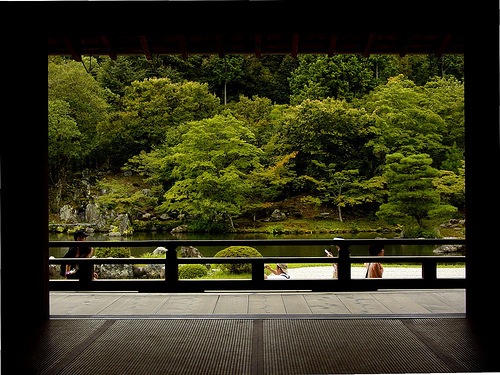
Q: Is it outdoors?
A: Yes, it is outdoors.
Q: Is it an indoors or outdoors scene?
A: It is outdoors.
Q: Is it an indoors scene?
A: No, it is outdoors.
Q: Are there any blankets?
A: No, there are no blankets.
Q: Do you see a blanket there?
A: No, there are no blankets.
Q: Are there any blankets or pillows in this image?
A: No, there are no blankets or pillows.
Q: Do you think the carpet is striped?
A: Yes, the carpet is striped.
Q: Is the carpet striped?
A: Yes, the carpet is striped.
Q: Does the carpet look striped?
A: Yes, the carpet is striped.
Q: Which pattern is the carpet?
A: The carpet is striped.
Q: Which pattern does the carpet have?
A: The carpet has striped pattern.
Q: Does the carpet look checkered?
A: No, the carpet is striped.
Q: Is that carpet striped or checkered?
A: The carpet is striped.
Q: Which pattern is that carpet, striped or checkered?
A: The carpet is striped.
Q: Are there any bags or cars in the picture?
A: No, there are no cars or bags.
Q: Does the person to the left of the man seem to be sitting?
A: Yes, the person is sitting.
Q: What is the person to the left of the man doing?
A: The person is sitting.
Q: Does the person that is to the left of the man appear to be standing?
A: No, the person is sitting.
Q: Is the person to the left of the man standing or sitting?
A: The person is sitting.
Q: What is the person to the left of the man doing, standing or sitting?
A: The person is sitting.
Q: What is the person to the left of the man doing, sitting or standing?
A: The person is sitting.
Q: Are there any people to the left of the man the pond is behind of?
A: Yes, there is a person to the left of the man.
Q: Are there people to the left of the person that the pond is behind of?
A: Yes, there is a person to the left of the man.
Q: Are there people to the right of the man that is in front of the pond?
A: No, the person is to the left of the man.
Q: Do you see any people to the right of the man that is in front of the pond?
A: No, the person is to the left of the man.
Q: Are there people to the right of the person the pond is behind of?
A: No, the person is to the left of the man.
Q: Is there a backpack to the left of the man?
A: No, there is a person to the left of the man.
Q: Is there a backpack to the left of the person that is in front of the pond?
A: No, there is a person to the left of the man.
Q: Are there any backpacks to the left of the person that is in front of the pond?
A: No, there is a person to the left of the man.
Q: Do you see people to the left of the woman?
A: Yes, there is a person to the left of the woman.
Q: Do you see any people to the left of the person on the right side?
A: Yes, there is a person to the left of the woman.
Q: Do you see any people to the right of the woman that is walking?
A: No, the person is to the left of the woman.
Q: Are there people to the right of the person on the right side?
A: No, the person is to the left of the woman.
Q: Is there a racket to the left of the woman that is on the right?
A: No, there is a person to the left of the woman.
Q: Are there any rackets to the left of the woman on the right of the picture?
A: No, there is a person to the left of the woman.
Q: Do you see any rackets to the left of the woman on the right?
A: No, there is a person to the left of the woman.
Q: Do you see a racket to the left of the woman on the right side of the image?
A: No, there is a person to the left of the woman.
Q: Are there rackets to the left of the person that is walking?
A: No, there is a person to the left of the woman.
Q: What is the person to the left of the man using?
A: The person is using a camera.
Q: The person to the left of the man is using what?
A: The person is using a camera.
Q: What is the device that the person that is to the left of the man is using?
A: The device is a camera.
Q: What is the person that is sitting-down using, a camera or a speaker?
A: The person is using a camera.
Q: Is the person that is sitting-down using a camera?
A: Yes, the person is using a camera.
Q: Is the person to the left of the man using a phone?
A: No, the person is using a camera.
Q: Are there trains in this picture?
A: No, there are no trains.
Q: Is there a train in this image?
A: No, there are no trains.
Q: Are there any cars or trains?
A: No, there are no trains or cars.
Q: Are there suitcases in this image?
A: No, there are no suitcases.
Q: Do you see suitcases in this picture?
A: No, there are no suitcases.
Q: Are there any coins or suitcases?
A: No, there are no suitcases or coins.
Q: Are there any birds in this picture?
A: No, there are no birds.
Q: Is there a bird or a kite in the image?
A: No, there are no birds or kites.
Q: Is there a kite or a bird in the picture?
A: No, there are no birds or kites.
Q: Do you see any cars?
A: No, there are no cars.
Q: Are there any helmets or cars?
A: No, there are no cars or helmets.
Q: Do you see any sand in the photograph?
A: Yes, there is sand.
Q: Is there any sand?
A: Yes, there is sand.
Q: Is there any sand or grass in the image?
A: Yes, there is sand.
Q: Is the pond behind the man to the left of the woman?
A: Yes, the pond is behind the man.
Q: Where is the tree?
A: The tree is on the shore.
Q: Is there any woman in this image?
A: Yes, there is a woman.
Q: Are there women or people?
A: Yes, there is a woman.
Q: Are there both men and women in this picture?
A: Yes, there are both a woman and a man.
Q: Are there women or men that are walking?
A: Yes, the woman is walking.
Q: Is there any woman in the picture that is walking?
A: Yes, there is a woman that is walking.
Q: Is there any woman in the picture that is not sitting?
A: Yes, there is a woman that is walking.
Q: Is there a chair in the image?
A: No, there are no chairs.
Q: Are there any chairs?
A: No, there are no chairs.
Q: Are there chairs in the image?
A: No, there are no chairs.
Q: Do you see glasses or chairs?
A: No, there are no chairs or glasses.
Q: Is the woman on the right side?
A: Yes, the woman is on the right of the image.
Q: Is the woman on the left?
A: No, the woman is on the right of the image.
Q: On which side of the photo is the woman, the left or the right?
A: The woman is on the right of the image.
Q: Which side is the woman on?
A: The woman is on the right of the image.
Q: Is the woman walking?
A: Yes, the woman is walking.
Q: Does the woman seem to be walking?
A: Yes, the woman is walking.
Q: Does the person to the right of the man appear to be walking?
A: Yes, the woman is walking.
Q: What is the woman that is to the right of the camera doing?
A: The woman is walking.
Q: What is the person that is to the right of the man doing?
A: The woman is walking.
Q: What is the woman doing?
A: The woman is walking.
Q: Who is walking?
A: The woman is walking.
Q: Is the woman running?
A: No, the woman is walking.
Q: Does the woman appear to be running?
A: No, the woman is walking.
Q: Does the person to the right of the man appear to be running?
A: No, the woman is walking.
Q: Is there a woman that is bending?
A: No, there is a woman but she is walking.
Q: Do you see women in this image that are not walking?
A: No, there is a woman but she is walking.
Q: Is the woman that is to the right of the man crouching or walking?
A: The woman is walking.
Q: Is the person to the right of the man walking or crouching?
A: The woman is walking.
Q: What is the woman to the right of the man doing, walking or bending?
A: The woman is walking.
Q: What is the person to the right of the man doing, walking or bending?
A: The woman is walking.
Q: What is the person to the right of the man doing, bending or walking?
A: The woman is walking.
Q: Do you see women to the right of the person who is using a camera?
A: Yes, there is a woman to the right of the person.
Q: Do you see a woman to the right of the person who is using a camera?
A: Yes, there is a woman to the right of the person.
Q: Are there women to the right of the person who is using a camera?
A: Yes, there is a woman to the right of the person.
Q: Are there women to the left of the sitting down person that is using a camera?
A: No, the woman is to the right of the person.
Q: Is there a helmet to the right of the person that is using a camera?
A: No, there is a woman to the right of the person.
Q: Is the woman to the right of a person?
A: Yes, the woman is to the right of a person.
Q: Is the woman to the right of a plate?
A: No, the woman is to the right of a person.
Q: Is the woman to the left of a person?
A: No, the woman is to the right of a person.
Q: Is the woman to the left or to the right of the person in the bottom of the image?
A: The woman is to the right of the person.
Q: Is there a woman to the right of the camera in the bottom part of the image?
A: Yes, there is a woman to the right of the camera.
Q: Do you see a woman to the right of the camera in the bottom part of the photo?
A: Yes, there is a woman to the right of the camera.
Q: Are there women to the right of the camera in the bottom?
A: Yes, there is a woman to the right of the camera.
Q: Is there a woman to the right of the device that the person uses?
A: Yes, there is a woman to the right of the camera.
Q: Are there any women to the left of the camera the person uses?
A: No, the woman is to the right of the camera.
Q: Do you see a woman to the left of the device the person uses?
A: No, the woman is to the right of the camera.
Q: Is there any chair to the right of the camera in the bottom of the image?
A: No, there is a woman to the right of the camera.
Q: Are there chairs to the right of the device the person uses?
A: No, there is a woman to the right of the camera.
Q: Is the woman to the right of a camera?
A: Yes, the woman is to the right of a camera.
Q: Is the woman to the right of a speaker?
A: No, the woman is to the right of a camera.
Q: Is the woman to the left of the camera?
A: No, the woman is to the right of the camera.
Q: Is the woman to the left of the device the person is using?
A: No, the woman is to the right of the camera.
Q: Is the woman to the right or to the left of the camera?
A: The woman is to the right of the camera.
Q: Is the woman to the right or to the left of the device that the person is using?
A: The woman is to the right of the camera.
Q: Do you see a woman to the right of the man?
A: Yes, there is a woman to the right of the man.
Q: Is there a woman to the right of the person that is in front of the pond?
A: Yes, there is a woman to the right of the man.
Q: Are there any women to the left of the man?
A: No, the woman is to the right of the man.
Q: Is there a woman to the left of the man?
A: No, the woman is to the right of the man.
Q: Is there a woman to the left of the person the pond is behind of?
A: No, the woman is to the right of the man.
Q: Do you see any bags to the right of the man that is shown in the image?
A: No, there is a woman to the right of the man.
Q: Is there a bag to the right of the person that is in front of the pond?
A: No, there is a woman to the right of the man.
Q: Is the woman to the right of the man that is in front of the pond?
A: Yes, the woman is to the right of the man.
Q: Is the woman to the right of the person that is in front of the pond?
A: Yes, the woman is to the right of the man.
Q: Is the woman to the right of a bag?
A: No, the woman is to the right of the man.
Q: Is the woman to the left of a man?
A: No, the woman is to the right of a man.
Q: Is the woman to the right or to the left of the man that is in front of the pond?
A: The woman is to the right of the man.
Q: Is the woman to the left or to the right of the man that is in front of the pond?
A: The woman is to the right of the man.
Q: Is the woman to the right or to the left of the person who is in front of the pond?
A: The woman is to the right of the man.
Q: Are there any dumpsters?
A: No, there are no dumpsters.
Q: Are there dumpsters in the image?
A: No, there are no dumpsters.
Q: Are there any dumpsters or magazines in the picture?
A: No, there are no dumpsters or magazines.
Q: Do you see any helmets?
A: No, there are no helmets.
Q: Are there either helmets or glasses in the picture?
A: No, there are no helmets or glasses.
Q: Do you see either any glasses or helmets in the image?
A: No, there are no helmets or glasses.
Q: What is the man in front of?
A: The man is in front of the pond.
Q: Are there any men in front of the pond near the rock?
A: Yes, there is a man in front of the pond.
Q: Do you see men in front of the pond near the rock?
A: Yes, there is a man in front of the pond.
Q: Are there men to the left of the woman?
A: Yes, there is a man to the left of the woman.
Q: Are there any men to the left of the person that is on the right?
A: Yes, there is a man to the left of the woman.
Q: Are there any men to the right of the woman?
A: No, the man is to the left of the woman.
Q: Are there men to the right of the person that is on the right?
A: No, the man is to the left of the woman.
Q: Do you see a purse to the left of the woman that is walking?
A: No, there is a man to the left of the woman.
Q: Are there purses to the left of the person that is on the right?
A: No, there is a man to the left of the woman.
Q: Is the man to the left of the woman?
A: Yes, the man is to the left of the woman.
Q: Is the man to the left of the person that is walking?
A: Yes, the man is to the left of the woman.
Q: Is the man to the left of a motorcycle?
A: No, the man is to the left of the woman.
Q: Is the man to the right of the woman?
A: No, the man is to the left of the woman.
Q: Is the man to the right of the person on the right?
A: No, the man is to the left of the woman.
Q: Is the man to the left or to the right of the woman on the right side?
A: The man is to the left of the woman.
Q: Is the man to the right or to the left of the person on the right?
A: The man is to the left of the woman.